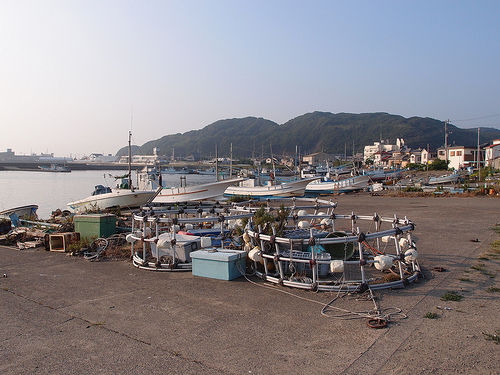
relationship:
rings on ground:
[129, 193, 421, 290] [0, 152, 497, 374]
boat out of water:
[63, 168, 162, 214] [30, 175, 90, 199]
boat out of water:
[111, 174, 248, 204] [3, 167, 240, 223]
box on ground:
[189, 248, 246, 280] [177, 273, 252, 308]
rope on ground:
[385, 313, 408, 318] [0, 247, 495, 372]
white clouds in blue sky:
[13, 17, 179, 147] [323, 11, 472, 106]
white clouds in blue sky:
[0, 0, 500, 158] [0, 0, 500, 159]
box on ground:
[189, 248, 247, 281] [83, 286, 322, 373]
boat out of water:
[113, 145, 172, 167] [2, 168, 307, 213]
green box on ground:
[72, 209, 113, 235] [0, 222, 265, 372]